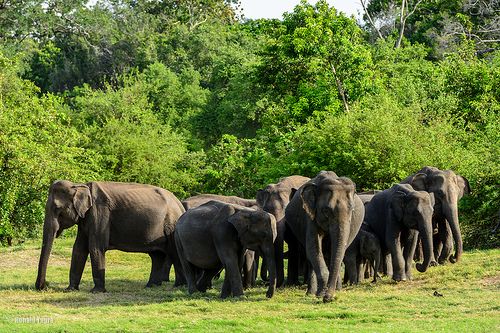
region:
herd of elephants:
[12, 153, 466, 288]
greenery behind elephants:
[2, 2, 499, 184]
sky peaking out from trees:
[234, 0, 368, 23]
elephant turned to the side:
[25, 173, 177, 281]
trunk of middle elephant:
[320, 218, 352, 310]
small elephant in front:
[162, 205, 284, 302]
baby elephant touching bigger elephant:
[347, 230, 388, 290]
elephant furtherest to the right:
[416, 157, 473, 257]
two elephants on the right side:
[366, 158, 476, 276]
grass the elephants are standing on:
[2, 228, 497, 332]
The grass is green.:
[1, 246, 499, 329]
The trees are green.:
[1, 1, 498, 251]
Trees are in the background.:
[1, 0, 498, 259]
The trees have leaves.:
[1, 0, 499, 253]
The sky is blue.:
[1, 0, 403, 47]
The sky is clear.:
[0, 0, 403, 39]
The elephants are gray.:
[35, 164, 465, 301]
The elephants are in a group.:
[33, 165, 466, 297]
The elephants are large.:
[30, 165, 465, 303]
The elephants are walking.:
[33, 165, 467, 304]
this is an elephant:
[36, 175, 172, 295]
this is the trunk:
[324, 207, 347, 298]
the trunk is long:
[34, 210, 61, 291]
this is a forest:
[0, 1, 455, 163]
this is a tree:
[280, 13, 322, 112]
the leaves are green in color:
[291, 37, 318, 80]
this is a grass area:
[348, 295, 470, 331]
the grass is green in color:
[355, 295, 420, 324]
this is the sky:
[245, 2, 277, 20]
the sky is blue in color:
[253, 4, 276, 16]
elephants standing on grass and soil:
[23, 158, 478, 306]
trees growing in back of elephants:
[27, 10, 483, 202]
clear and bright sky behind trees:
[237, 0, 369, 20]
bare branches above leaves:
[317, 1, 494, 52]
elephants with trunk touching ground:
[30, 151, 110, 297]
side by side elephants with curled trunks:
[377, 160, 472, 281]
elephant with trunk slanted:
[290, 165, 360, 300]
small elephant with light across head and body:
[165, 195, 285, 300]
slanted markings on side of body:
[100, 181, 161, 211]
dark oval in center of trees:
[17, 38, 139, 96]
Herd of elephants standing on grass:
[37, 165, 464, 302]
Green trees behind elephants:
[131, 18, 261, 165]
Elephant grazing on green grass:
[35, 179, 174, 291]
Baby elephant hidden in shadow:
[344, 231, 383, 287]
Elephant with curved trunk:
[369, 182, 434, 284]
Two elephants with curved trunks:
[401, 165, 469, 280]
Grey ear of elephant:
[69, 182, 96, 219]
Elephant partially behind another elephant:
[185, 192, 255, 208]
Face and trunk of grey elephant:
[295, 171, 357, 301]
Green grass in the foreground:
[88, 308, 475, 325]